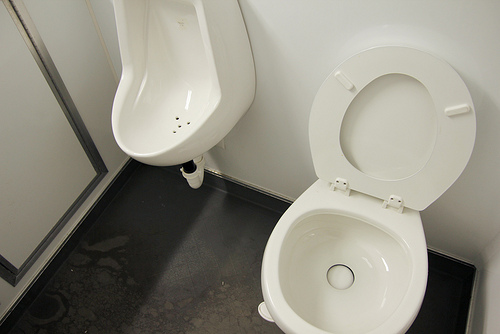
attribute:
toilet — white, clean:
[261, 44, 478, 333]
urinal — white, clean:
[108, 0, 257, 168]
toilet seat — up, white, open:
[306, 44, 477, 213]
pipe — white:
[180, 153, 205, 190]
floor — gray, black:
[7, 163, 465, 334]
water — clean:
[294, 228, 381, 319]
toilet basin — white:
[260, 181, 429, 333]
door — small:
[0, 1, 102, 277]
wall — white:
[0, 2, 132, 325]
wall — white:
[88, 1, 498, 268]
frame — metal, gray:
[1, 1, 109, 288]